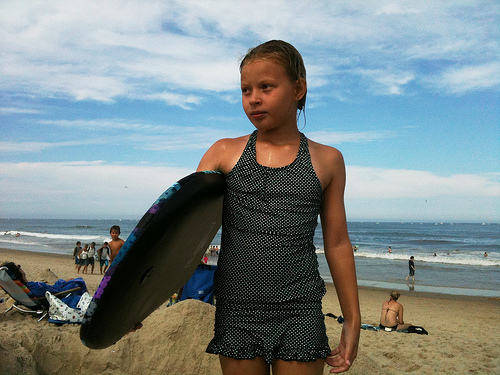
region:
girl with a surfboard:
[83, 31, 385, 363]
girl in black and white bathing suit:
[188, 38, 368, 373]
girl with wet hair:
[190, 29, 353, 129]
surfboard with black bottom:
[74, 104, 241, 346]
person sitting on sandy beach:
[366, 259, 423, 364]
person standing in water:
[381, 183, 447, 290]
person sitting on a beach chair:
[3, 246, 97, 336]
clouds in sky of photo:
[18, 12, 483, 174]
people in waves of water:
[409, 211, 499, 286]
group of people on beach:
[38, 216, 138, 300]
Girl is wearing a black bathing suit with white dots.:
[190, 110, 335, 360]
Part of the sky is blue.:
[425, 105, 490, 150]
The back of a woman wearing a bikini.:
[375, 275, 410, 335]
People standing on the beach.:
[60, 230, 105, 270]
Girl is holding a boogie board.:
[70, 156, 230, 356]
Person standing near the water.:
[395, 250, 430, 280]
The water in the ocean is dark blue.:
[355, 220, 480, 247]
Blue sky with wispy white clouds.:
[33, 70, 225, 128]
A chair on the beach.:
[0, 258, 85, 323]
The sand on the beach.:
[401, 339, 493, 374]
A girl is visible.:
[216, 61, 350, 358]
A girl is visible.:
[217, 10, 308, 265]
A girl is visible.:
[188, 108, 272, 363]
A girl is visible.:
[236, 70, 291, 369]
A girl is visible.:
[279, 119, 317, 364]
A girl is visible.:
[243, 106, 334, 311]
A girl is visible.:
[236, 225, 266, 356]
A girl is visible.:
[252, 191, 308, 349]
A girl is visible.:
[211, 116, 266, 280]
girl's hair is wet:
[186, 26, 338, 135]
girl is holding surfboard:
[39, 3, 481, 360]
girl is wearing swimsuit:
[63, 3, 430, 370]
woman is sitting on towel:
[376, 266, 448, 349]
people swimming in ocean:
[353, 225, 494, 294]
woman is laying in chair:
[1, 249, 106, 312]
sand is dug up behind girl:
[1, 288, 244, 373]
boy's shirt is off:
[93, 215, 131, 255]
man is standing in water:
[401, 244, 426, 299]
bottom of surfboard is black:
[78, 151, 268, 316]